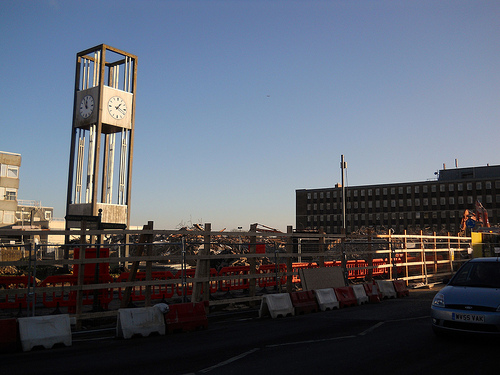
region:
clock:
[72, 52, 143, 140]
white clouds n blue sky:
[164, 152, 194, 186]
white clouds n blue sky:
[195, 39, 236, 73]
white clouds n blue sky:
[387, 42, 418, 73]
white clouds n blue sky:
[264, 18, 341, 98]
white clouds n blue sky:
[178, 89, 253, 157]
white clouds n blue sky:
[237, 56, 285, 93]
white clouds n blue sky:
[254, 71, 292, 106]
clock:
[85, 92, 136, 136]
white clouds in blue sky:
[191, 42, 233, 82]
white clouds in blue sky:
[240, 108, 267, 148]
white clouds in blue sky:
[208, 82, 248, 133]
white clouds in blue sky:
[197, 133, 252, 178]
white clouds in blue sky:
[345, 36, 417, 93]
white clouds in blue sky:
[241, 18, 308, 83]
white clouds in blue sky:
[171, 52, 225, 119]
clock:
[85, 79, 143, 157]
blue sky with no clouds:
[184, 53, 231, 94]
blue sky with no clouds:
[227, 93, 282, 133]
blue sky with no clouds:
[398, 49, 470, 96]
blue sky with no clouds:
[231, 29, 306, 71]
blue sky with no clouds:
[155, 138, 235, 189]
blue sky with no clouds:
[210, 86, 277, 160]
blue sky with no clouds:
[181, 36, 251, 108]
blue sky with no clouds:
[194, 55, 272, 116]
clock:
[62, 64, 126, 124]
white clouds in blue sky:
[187, 23, 237, 61]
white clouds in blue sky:
[195, 73, 240, 124]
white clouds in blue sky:
[182, 166, 236, 224]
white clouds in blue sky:
[235, 18, 282, 75]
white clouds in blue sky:
[335, 22, 405, 127]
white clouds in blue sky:
[205, 21, 267, 79]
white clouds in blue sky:
[354, 62, 471, 164]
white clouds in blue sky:
[205, 131, 253, 152]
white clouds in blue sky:
[215, 42, 303, 109]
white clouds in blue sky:
[348, 89, 432, 134]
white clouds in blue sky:
[221, 73, 278, 114]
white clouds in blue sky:
[165, 26, 222, 101]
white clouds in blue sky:
[244, 52, 298, 122]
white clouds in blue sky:
[232, 39, 280, 99]